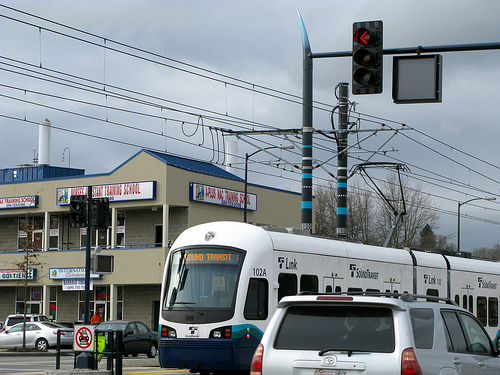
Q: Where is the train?
A: On the tracks.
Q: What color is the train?
A: White.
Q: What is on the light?
A: Arrow.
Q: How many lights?
A: 1.